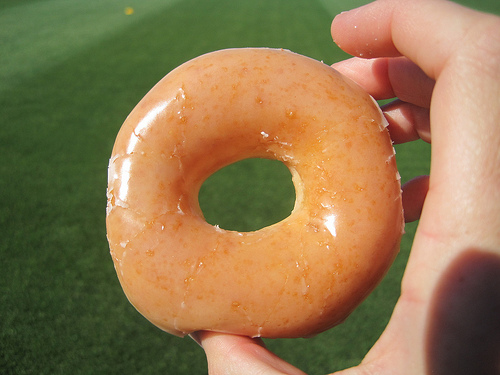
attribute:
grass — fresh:
[0, 0, 499, 373]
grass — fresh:
[19, 184, 73, 261]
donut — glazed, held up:
[93, 45, 413, 337]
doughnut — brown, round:
[102, 42, 409, 336]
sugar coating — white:
[310, 186, 354, 248]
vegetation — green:
[37, 7, 497, 352]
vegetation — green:
[0, 1, 497, 371]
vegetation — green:
[17, 13, 105, 273]